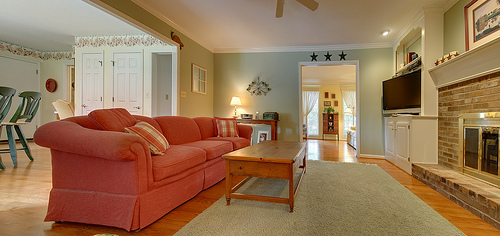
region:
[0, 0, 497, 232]
A beautiful modern looking living room.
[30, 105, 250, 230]
A beautiful pink sofa.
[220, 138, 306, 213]
A wooden table inside a living room.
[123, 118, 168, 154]
A colorful pillow is laying on a sofa.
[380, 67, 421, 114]
A flat screen television.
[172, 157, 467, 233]
A grey rug under the table.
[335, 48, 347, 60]
A single star is above a door.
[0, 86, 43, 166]
Two chairs are placed next to each other.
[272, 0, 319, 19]
Two helixes from a ceiling fan.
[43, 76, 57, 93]
A red plate is hanged on the wall.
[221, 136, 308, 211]
A wooden coffee table.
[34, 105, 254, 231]
A large peach colored sofa.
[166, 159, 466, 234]
A light grey colored rug underneath of the coffee table.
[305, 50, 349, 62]
Star wall art hung above a door entrance.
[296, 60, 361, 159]
A large white door frame.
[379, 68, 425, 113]
A silver flat screen TV, turned off.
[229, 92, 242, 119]
A small lamp lit up on a table.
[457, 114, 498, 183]
A fireplace with glass sliding doors.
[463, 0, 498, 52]
A picture hanging above the fireplace.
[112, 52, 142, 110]
A white door.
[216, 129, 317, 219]
Wooden table on top of rug.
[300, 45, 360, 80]
Three decorative stars above doorway.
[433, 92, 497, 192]
Brick fireplace.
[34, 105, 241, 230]
Couch with two plaid pillows.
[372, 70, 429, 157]
Television set on top of white cabinet.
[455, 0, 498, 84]
Framed Picture over mantle.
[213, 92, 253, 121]
Table lamp on in corner of room.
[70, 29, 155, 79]
Wallpaper border over white doors.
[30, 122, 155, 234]
Arm of orange couch.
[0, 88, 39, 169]
Green and beige chair.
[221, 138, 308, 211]
wooden coffee table on rug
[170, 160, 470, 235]
white rug on hardwood floor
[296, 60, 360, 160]
large open entryway in wall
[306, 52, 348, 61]
three large black stars above doorway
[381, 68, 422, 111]
large black television in corner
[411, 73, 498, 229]
several bricks on fireplace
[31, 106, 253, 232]
pink couch on hardwood floor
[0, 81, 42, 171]
green chairs behind couch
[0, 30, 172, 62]
border on top of wall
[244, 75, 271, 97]
wall art mounted on wall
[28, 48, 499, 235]
a family room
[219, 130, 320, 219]
a wooden coffee table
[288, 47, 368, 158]
a door with tree stars on top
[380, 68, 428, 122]
a flat screen tv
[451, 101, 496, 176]
a fireplace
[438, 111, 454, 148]
a brick wall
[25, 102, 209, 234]
a couch with pillows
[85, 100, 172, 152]
pillows on top of the couch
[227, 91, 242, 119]
a lampshade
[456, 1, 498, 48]
a picture frame on the mantle